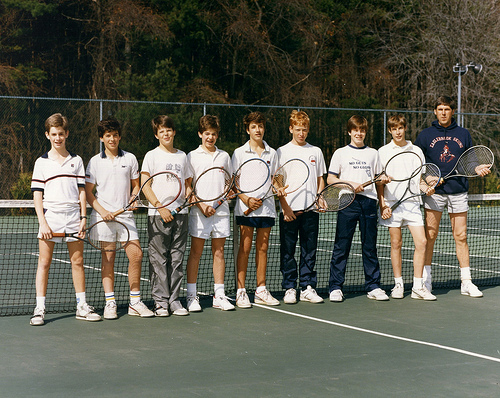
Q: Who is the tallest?
A: Boy in blue top.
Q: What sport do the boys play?
A: Tennis.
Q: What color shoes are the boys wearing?
A: White.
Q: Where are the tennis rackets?
A: In the boy's hands.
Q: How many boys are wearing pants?
A: Three.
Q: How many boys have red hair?
A: One boy.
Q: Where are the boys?
A: On tennis court.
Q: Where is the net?
A: Behind the boys.